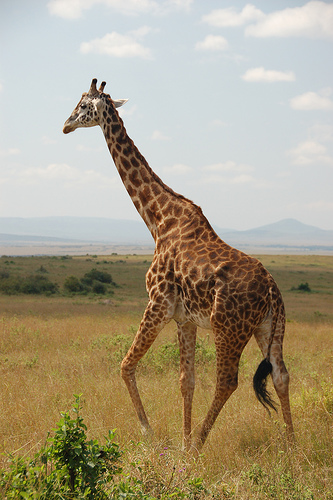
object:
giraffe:
[63, 78, 296, 460]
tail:
[252, 288, 280, 416]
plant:
[0, 367, 115, 498]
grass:
[233, 440, 277, 498]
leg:
[194, 312, 250, 457]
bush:
[289, 279, 311, 292]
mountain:
[238, 217, 332, 247]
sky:
[132, 0, 332, 142]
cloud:
[243, 63, 295, 81]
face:
[62, 92, 91, 134]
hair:
[252, 358, 280, 418]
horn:
[90, 78, 98, 93]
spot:
[135, 185, 154, 207]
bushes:
[0, 265, 60, 297]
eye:
[80, 103, 87, 111]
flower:
[12, 457, 40, 490]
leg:
[120, 295, 174, 435]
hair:
[112, 106, 123, 126]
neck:
[105, 114, 180, 233]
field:
[0, 0, 332, 498]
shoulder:
[145, 252, 175, 297]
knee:
[119, 357, 135, 383]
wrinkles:
[152, 220, 184, 234]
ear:
[112, 98, 129, 107]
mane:
[159, 178, 172, 193]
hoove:
[184, 455, 196, 469]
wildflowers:
[41, 455, 89, 500]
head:
[62, 77, 129, 134]